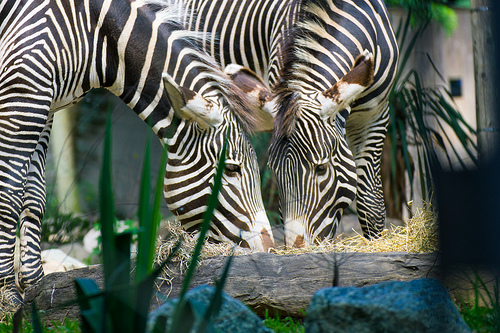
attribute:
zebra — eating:
[0, 0, 278, 315]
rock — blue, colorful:
[297, 279, 470, 332]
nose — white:
[245, 209, 278, 253]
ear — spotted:
[318, 48, 377, 118]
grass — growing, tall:
[1, 265, 499, 333]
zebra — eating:
[157, 0, 400, 252]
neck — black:
[95, 0, 249, 147]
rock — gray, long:
[24, 255, 499, 320]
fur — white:
[0, 1, 275, 312]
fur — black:
[159, 0, 399, 251]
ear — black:
[159, 70, 222, 130]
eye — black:
[219, 158, 244, 179]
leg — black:
[0, 106, 49, 317]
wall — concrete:
[71, 0, 480, 220]